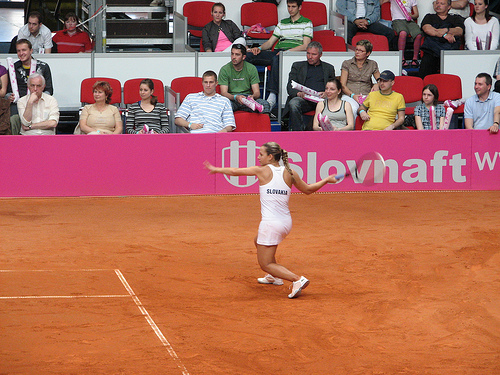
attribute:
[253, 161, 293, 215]
top — white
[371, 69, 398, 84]
hat — blue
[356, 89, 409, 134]
shirt — yellow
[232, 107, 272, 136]
seat — empty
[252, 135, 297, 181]
hair — dirty blonde, braided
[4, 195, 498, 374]
court — clay, orange, dirt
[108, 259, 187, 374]
line — white, painted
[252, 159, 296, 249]
dress — white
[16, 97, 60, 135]
shirt — long sleeved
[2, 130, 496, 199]
sign — pink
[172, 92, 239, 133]
shirt — striped, plaid